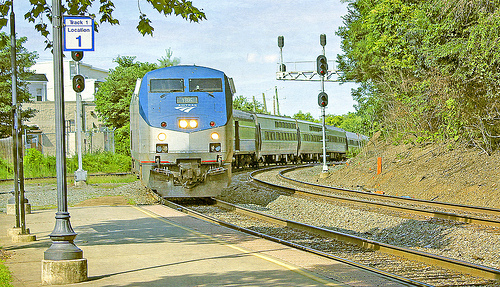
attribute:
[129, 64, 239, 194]
locomotive — blue, silver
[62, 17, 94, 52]
sign — blue, white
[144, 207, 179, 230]
line — yellow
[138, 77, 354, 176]
train — long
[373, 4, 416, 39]
leaves — green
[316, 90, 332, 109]
traffic signal — unlit